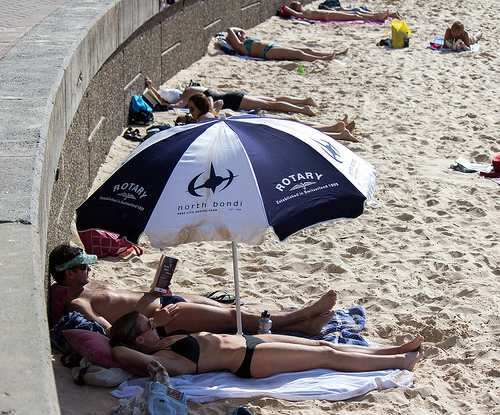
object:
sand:
[67, 0, 499, 414]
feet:
[303, 288, 336, 321]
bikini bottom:
[231, 332, 265, 378]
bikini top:
[170, 330, 200, 373]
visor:
[57, 252, 98, 270]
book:
[149, 252, 179, 293]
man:
[48, 244, 337, 337]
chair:
[76, 227, 143, 257]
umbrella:
[75, 113, 377, 248]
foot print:
[420, 208, 455, 236]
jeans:
[50, 309, 108, 351]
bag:
[391, 21, 410, 48]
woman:
[107, 310, 424, 379]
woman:
[224, 26, 349, 61]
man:
[441, 20, 482, 52]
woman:
[143, 75, 319, 118]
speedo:
[155, 292, 187, 337]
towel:
[109, 366, 414, 401]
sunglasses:
[68, 262, 89, 268]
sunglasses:
[145, 318, 154, 331]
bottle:
[258, 310, 272, 333]